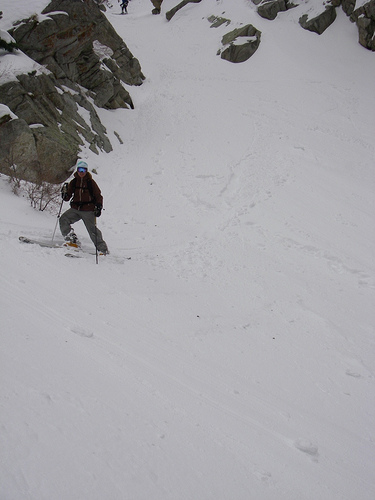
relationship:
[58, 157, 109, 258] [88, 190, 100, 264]
man holding ski poles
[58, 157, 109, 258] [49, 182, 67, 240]
man holding ski poles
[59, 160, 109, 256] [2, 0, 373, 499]
man on mountain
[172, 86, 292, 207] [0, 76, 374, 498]
snow covering ground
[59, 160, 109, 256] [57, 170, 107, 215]
man wearing jacket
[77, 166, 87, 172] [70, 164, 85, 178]
ski goggles on face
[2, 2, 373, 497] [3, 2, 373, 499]
ground covered in snow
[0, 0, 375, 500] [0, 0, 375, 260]
snow on hill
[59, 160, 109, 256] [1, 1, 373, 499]
man on ski slope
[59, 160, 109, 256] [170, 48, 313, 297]
man skiing down hill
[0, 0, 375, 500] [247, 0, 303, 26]
snow on rock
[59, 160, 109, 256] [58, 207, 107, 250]
man wearing pants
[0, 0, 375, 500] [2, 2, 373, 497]
snow on ground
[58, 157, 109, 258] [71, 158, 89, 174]
man wearing hat